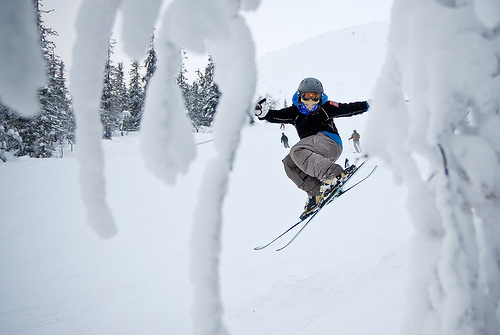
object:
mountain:
[0, 0, 498, 332]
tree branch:
[187, 17, 259, 334]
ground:
[0, 15, 415, 335]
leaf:
[187, 15, 256, 335]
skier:
[251, 76, 373, 219]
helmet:
[294, 77, 324, 103]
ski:
[252, 163, 381, 252]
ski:
[272, 158, 368, 251]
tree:
[112, 60, 127, 131]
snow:
[0, 0, 499, 334]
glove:
[253, 95, 272, 120]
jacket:
[264, 99, 367, 139]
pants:
[280, 132, 345, 200]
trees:
[0, 0, 69, 157]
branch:
[101, 32, 123, 139]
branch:
[0, 0, 74, 162]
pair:
[252, 162, 380, 255]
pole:
[347, 135, 352, 154]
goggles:
[302, 92, 321, 102]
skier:
[277, 131, 290, 150]